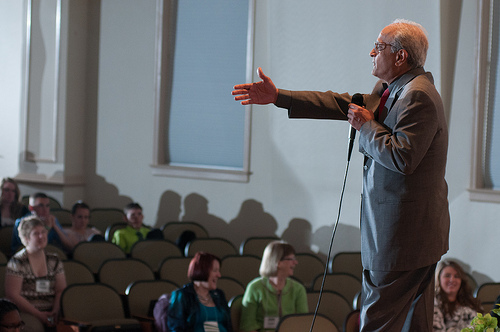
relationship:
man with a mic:
[327, 39, 469, 328] [339, 91, 369, 167]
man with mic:
[327, 39, 469, 328] [339, 91, 369, 167]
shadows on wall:
[151, 188, 309, 250] [128, 160, 323, 204]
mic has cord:
[339, 91, 369, 167] [326, 165, 356, 274]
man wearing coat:
[327, 39, 469, 328] [360, 96, 437, 267]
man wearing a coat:
[327, 39, 469, 328] [360, 96, 437, 267]